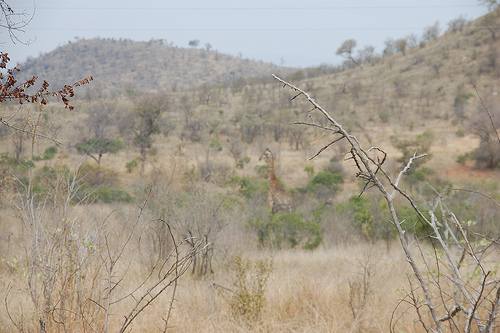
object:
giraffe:
[258, 148, 294, 213]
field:
[2, 95, 499, 332]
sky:
[1, 1, 499, 71]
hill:
[2, 39, 327, 98]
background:
[0, 0, 497, 98]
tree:
[0, 57, 91, 109]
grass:
[3, 101, 498, 332]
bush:
[2, 166, 215, 333]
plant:
[466, 72, 498, 332]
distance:
[0, 2, 499, 98]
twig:
[273, 76, 498, 330]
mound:
[318, 1, 496, 79]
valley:
[237, 58, 382, 97]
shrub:
[306, 164, 345, 202]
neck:
[268, 158, 275, 183]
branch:
[273, 224, 390, 333]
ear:
[265, 147, 272, 154]